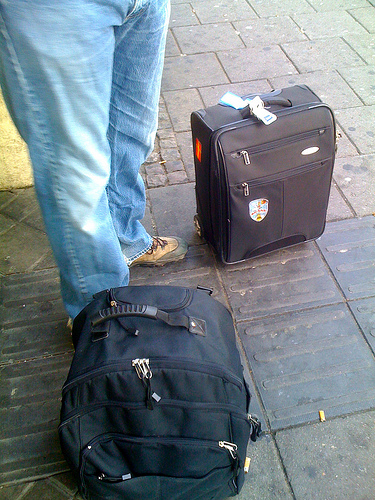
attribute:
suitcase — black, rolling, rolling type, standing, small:
[191, 85, 338, 267]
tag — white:
[249, 103, 275, 126]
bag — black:
[57, 286, 262, 500]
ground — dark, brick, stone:
[0, 2, 374, 499]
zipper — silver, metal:
[130, 356, 152, 379]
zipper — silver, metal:
[219, 438, 240, 459]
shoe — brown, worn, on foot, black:
[130, 236, 188, 268]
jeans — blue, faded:
[1, 0, 170, 321]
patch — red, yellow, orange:
[193, 137, 201, 161]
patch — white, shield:
[248, 198, 269, 223]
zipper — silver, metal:
[240, 150, 251, 166]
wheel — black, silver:
[192, 214, 204, 239]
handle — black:
[89, 304, 208, 340]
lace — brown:
[145, 237, 166, 255]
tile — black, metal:
[236, 306, 374, 432]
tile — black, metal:
[216, 241, 346, 320]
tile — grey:
[3, 223, 52, 274]